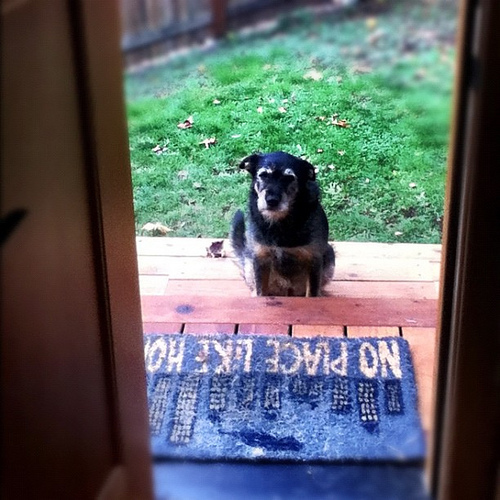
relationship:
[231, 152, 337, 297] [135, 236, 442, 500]
dog sitting on floor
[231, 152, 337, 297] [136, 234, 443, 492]
dog sitting on deck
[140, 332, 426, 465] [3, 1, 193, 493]
doormat in front of door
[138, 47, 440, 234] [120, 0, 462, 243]
grass in yard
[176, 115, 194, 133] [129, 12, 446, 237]
leaf in yard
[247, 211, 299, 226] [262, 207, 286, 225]
beard on chin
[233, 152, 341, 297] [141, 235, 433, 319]
dog sitting on door step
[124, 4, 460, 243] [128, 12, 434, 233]
grass in yard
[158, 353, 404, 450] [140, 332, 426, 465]
buildings on doormat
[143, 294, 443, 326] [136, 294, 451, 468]
wooden plank on door step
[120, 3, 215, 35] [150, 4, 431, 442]
fence enclosing outside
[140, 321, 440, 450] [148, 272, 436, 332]
doormat on step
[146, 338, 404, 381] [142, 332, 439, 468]
letters on mat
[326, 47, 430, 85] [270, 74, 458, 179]
leaves on grass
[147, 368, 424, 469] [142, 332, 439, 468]
drawings on mat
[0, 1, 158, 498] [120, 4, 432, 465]
door leads to outside